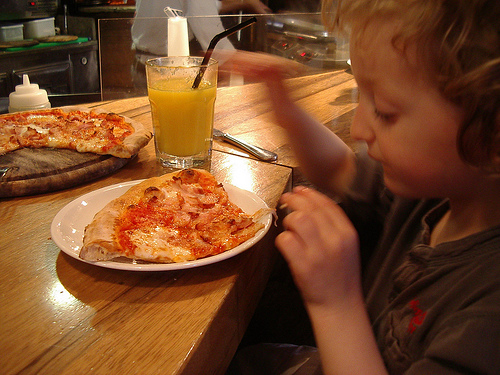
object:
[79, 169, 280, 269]
pizza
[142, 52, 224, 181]
glass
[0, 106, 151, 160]
pizza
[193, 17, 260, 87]
straw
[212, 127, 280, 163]
knife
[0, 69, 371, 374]
table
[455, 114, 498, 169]
headphones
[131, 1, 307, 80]
man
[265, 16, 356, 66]
oven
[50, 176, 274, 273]
plate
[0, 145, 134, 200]
cutting board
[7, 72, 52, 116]
bottle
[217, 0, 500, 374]
boy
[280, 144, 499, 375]
shirt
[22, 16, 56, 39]
bins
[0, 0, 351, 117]
background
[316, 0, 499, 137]
hair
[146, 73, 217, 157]
drink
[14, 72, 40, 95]
top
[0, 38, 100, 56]
counter